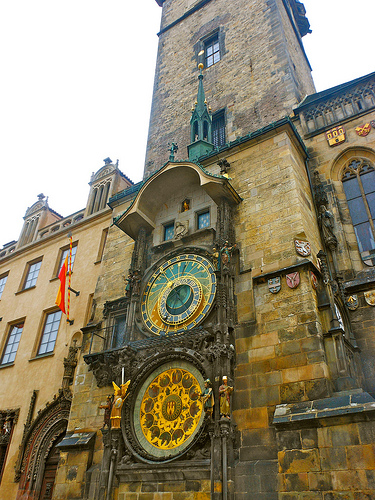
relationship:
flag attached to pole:
[56, 257, 68, 313] [65, 234, 73, 327]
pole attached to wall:
[65, 234, 73, 327] [0, 210, 111, 440]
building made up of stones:
[9, 76, 358, 440] [255, 158, 306, 250]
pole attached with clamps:
[65, 233, 71, 329] [67, 285, 79, 292]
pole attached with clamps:
[65, 233, 71, 329] [63, 318, 74, 323]